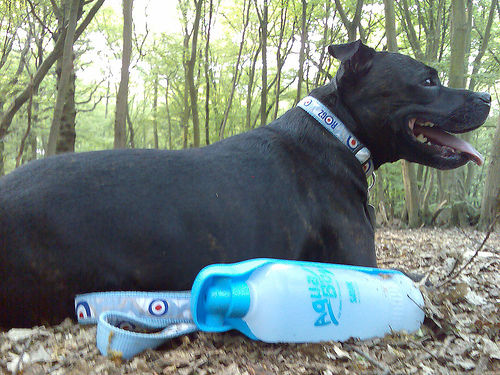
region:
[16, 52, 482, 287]
a large dog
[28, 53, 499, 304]
a black dog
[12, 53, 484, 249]
a dog with a collar on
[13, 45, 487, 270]
a dog laying down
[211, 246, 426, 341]
a water bottle next to the dog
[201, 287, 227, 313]
the lid on the water bottle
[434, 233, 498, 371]
leaves on the ground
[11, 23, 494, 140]
trees behind the dog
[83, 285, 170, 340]
a strap on the water bottle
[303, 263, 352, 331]
writing on the water bottle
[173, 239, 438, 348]
this is a plastic bottle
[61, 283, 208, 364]
this is a dog leash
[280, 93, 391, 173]
this is a dog collar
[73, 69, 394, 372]
the leash and the collar match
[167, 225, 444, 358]
the blue plastic on the bottle can be used as a water bowl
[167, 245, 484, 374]
a water bottle and bowl for dogs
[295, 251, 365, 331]
the letters on the bottle are blue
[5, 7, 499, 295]
this is a large black dog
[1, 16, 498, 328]
the dog is on the ground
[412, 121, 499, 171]
this is the dog's tongue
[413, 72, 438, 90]
the eye of a dog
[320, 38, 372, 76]
the ear of a dog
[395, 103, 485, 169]
the mouth of a dog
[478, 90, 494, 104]
the nose of a dog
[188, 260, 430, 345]
a blue bottle on the ground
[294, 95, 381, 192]
a light blue collar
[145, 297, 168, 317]
a small target symbol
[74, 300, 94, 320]
a small target symbol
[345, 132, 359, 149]
a small target symbol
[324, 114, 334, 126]
a small target symbol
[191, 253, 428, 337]
water bottle on the ground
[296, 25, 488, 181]
Head of a big black dog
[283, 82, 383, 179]
collar on neck of dog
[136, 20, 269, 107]
sparse green trees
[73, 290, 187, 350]
Leash for walking dog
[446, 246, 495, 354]
Brown dead leaves on the ground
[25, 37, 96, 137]
skinny tree trunks behind the dog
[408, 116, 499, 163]
Dog with tongue hanging out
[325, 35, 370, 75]
Pointed ear of dog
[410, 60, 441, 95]
Black eye of dog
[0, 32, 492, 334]
A dog in the foreground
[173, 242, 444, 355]
A water bottle in the foreground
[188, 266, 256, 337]
Top of the bottle is light blue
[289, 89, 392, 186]
Dog is wearing a collar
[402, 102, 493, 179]
Dog's mouth is open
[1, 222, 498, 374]
Fallen leaves are on the ground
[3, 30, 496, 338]
The dog coat is black in color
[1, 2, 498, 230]
Tall trees in the background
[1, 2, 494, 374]
Photo was taken in a woodland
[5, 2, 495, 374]
Photo was taken outdoors